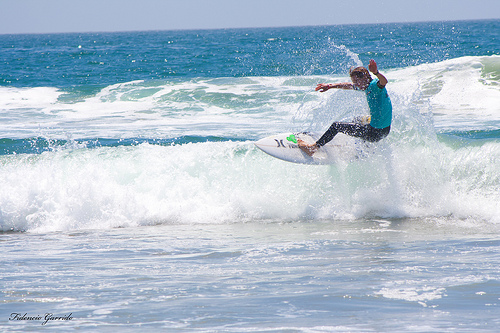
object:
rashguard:
[351, 79, 392, 130]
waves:
[0, 132, 112, 233]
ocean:
[0, 19, 499, 333]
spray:
[300, 42, 444, 169]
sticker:
[286, 134, 298, 144]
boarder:
[296, 58, 393, 156]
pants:
[312, 119, 389, 155]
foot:
[296, 138, 316, 157]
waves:
[383, 123, 499, 224]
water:
[0, 17, 500, 333]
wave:
[0, 126, 483, 227]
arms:
[370, 73, 391, 90]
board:
[254, 127, 376, 164]